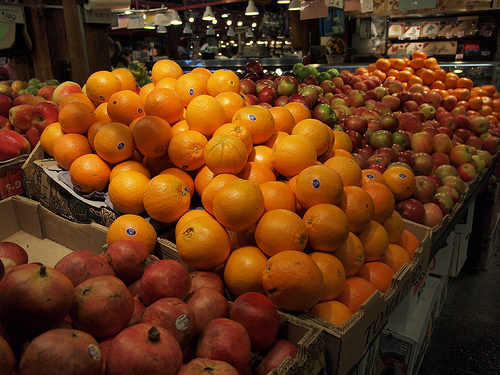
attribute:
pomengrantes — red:
[103, 254, 219, 354]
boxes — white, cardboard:
[361, 188, 481, 374]